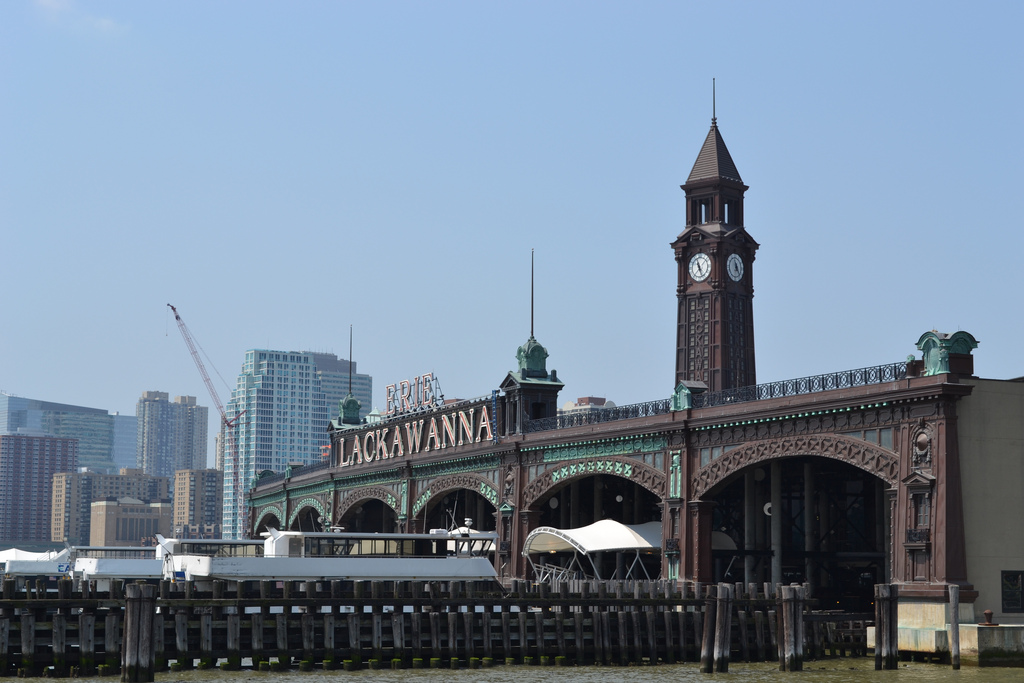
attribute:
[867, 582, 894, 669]
posts — wood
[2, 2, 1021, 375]
skies — blue